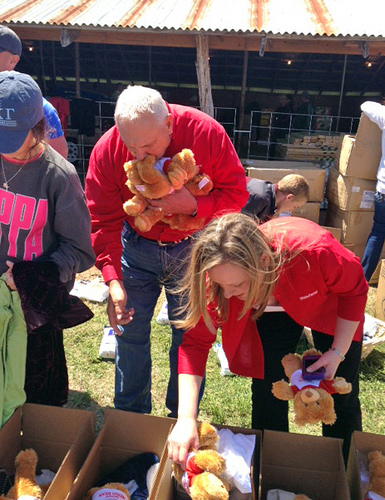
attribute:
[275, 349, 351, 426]
bear — brown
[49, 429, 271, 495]
teddy bears — teddy 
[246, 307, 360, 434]
pants — black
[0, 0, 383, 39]
rusted roof — metallic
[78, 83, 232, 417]
man — holding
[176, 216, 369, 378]
shirt — red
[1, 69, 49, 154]
hat — blue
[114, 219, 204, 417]
pants — blue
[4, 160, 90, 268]
shirt — gray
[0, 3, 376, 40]
roof — rusty